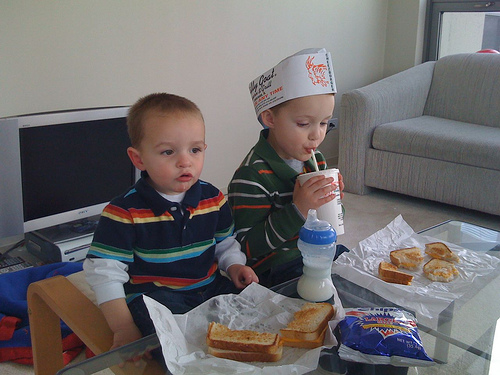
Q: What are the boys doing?
A: Eating.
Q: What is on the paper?
A: Sandwiches.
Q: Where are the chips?
A: Table.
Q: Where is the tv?
A: Behind the boys.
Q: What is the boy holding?
A: A cup.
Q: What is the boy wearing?
A: Hat.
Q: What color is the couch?
A: Gray.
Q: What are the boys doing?
A: Eating.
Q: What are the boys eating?
A: Grilled cheese.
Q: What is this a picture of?
A: Two boys eating.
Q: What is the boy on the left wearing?
A: Blue collared and striped short sleeve shirt.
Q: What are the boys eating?
A: Sandwich.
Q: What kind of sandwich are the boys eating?
A: Grilled cheese.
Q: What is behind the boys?
A: TV.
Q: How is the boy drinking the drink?
A: Through straw.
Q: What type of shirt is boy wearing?
A: Striped.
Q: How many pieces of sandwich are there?
A: Four.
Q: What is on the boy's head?
A: Paper hat.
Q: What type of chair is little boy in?
A: High chair.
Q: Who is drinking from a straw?
A: A boy.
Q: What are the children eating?
A: Sandwiches.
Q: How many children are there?
A: Two.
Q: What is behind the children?
A: Television.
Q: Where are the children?
A: Living room.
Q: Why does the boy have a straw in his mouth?
A: To drink.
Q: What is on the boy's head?
A: A paper hat.